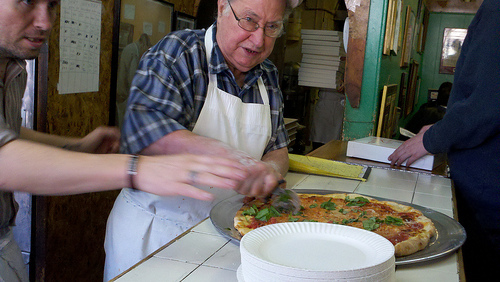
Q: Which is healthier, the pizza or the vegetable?
A: The vegetable is healthier than the pizza.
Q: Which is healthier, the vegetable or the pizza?
A: The vegetable is healthier than the pizza.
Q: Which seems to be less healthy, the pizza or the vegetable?
A: The pizza is less healthy than the vegetable.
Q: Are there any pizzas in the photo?
A: Yes, there is a pizza.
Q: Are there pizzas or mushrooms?
A: Yes, there is a pizza.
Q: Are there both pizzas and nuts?
A: No, there is a pizza but no nuts.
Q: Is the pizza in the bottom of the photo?
A: Yes, the pizza is in the bottom of the image.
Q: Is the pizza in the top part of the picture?
A: No, the pizza is in the bottom of the image.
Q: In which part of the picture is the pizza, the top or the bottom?
A: The pizza is in the bottom of the image.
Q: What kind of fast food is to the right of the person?
A: The food is a pizza.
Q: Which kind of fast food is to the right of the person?
A: The food is a pizza.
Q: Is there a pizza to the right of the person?
A: Yes, there is a pizza to the right of the person.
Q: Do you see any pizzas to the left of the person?
A: No, the pizza is to the right of the person.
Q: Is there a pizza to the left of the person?
A: No, the pizza is to the right of the person.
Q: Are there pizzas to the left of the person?
A: No, the pizza is to the right of the person.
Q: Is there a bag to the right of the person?
A: No, there is a pizza to the right of the person.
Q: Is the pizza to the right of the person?
A: Yes, the pizza is to the right of the person.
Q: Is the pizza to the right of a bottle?
A: No, the pizza is to the right of the person.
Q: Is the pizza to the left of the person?
A: No, the pizza is to the right of the person.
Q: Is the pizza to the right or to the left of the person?
A: The pizza is to the right of the person.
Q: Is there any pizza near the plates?
A: Yes, there is a pizza near the plates.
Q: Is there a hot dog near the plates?
A: No, there is a pizza near the plates.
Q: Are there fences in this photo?
A: No, there are no fences.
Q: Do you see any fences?
A: No, there are no fences.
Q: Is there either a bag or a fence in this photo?
A: No, there are no fences or bags.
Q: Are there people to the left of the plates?
A: Yes, there is a person to the left of the plates.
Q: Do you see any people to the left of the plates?
A: Yes, there is a person to the left of the plates.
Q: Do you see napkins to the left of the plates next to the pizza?
A: No, there is a person to the left of the plates.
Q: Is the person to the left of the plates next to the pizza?
A: Yes, the person is to the left of the plates.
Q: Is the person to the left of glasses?
A: No, the person is to the left of the plates.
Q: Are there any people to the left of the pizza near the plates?
A: Yes, there is a person to the left of the pizza.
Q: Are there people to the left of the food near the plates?
A: Yes, there is a person to the left of the pizza.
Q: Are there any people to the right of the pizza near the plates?
A: No, the person is to the left of the pizza.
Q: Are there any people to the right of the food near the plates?
A: No, the person is to the left of the pizza.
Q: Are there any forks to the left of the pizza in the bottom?
A: No, there is a person to the left of the pizza.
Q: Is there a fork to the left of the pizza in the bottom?
A: No, there is a person to the left of the pizza.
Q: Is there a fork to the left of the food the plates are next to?
A: No, there is a person to the left of the pizza.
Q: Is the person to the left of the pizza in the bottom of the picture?
A: Yes, the person is to the left of the pizza.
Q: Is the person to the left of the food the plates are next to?
A: Yes, the person is to the left of the pizza.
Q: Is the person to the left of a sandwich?
A: No, the person is to the left of the pizza.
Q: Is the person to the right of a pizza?
A: No, the person is to the left of a pizza.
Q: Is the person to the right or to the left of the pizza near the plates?
A: The person is to the left of the pizza.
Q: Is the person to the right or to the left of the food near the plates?
A: The person is to the left of the pizza.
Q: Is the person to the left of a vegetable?
A: Yes, the person is to the left of a vegetable.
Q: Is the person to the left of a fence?
A: No, the person is to the left of a vegetable.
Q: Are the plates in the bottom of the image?
A: Yes, the plates are in the bottom of the image.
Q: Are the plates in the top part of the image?
A: No, the plates are in the bottom of the image.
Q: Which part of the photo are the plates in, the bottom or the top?
A: The plates are in the bottom of the image.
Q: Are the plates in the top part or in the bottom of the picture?
A: The plates are in the bottom of the image.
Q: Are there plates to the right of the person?
A: Yes, there are plates to the right of the person.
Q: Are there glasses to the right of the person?
A: No, there are plates to the right of the person.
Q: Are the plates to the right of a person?
A: Yes, the plates are to the right of a person.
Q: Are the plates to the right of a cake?
A: No, the plates are to the right of a person.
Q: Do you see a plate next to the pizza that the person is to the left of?
A: Yes, there are plates next to the pizza.